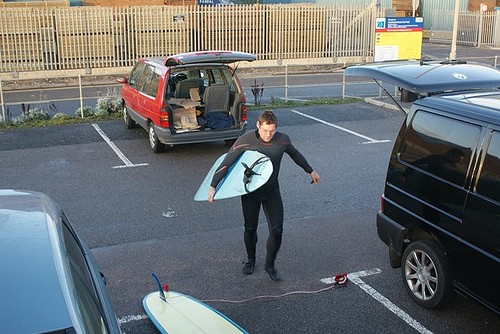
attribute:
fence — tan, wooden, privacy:
[2, 5, 395, 71]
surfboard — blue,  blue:
[192, 149, 274, 202]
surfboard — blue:
[186, 146, 275, 201]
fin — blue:
[148, 269, 170, 302]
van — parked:
[118, 51, 255, 148]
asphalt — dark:
[86, 120, 137, 197]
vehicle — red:
[109, 42, 263, 154]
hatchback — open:
[162, 47, 254, 137]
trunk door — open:
[162, 47, 256, 63]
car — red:
[131, 35, 243, 140]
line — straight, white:
[85, 117, 150, 172]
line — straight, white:
[344, 277, 409, 332]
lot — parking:
[4, 97, 484, 331]